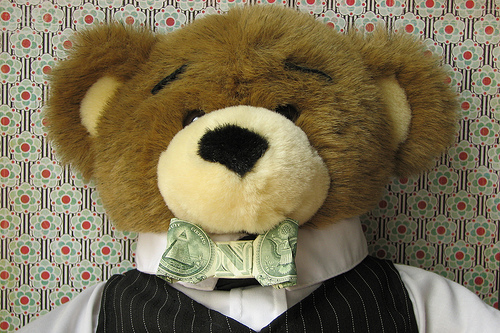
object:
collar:
[132, 215, 372, 293]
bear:
[33, 11, 499, 293]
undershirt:
[6, 212, 499, 332]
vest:
[99, 270, 429, 332]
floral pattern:
[0, 185, 73, 277]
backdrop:
[1, 3, 498, 331]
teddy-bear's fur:
[44, 1, 456, 235]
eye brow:
[149, 60, 189, 98]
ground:
[344, 101, 429, 156]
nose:
[204, 126, 275, 176]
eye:
[273, 104, 298, 122]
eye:
[180, 109, 202, 127]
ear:
[44, 27, 148, 187]